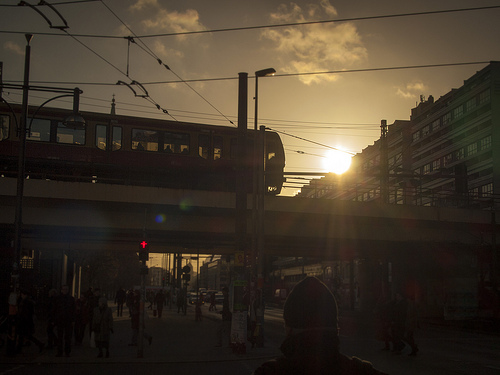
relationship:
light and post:
[247, 51, 285, 91] [247, 71, 270, 163]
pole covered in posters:
[219, 228, 262, 357] [219, 264, 248, 349]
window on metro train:
[155, 130, 182, 160] [1, 102, 288, 198]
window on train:
[133, 132, 160, 161] [1, 86, 295, 209]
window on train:
[113, 128, 129, 157] [1, 86, 295, 209]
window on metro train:
[88, 123, 108, 155] [1, 102, 288, 198]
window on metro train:
[52, 126, 79, 149] [1, 102, 288, 198]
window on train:
[4, 99, 285, 208] [28, 112, 46, 144]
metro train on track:
[1, 102, 288, 198] [13, 174, 494, 299]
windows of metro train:
[13, 115, 243, 162] [1, 102, 288, 198]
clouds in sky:
[117, 6, 444, 131] [6, 8, 496, 277]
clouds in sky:
[117, 4, 451, 144] [6, 8, 496, 277]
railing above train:
[19, 19, 499, 91] [6, 103, 296, 219]